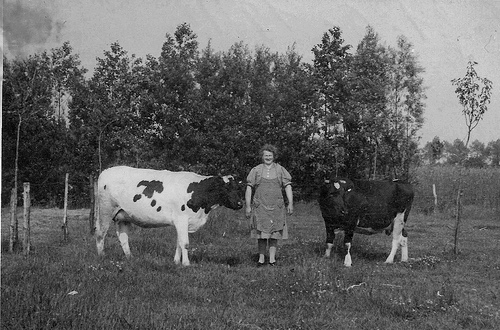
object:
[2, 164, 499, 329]
field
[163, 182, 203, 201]
black and white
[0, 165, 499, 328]
grass in  photo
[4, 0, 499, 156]
sky inphoto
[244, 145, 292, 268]
middle aged woman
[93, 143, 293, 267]
woman with a cow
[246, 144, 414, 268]
woman with a cow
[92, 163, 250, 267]
cows on grass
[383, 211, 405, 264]
cow with white legs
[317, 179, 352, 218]
black head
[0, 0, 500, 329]
picture of a farmer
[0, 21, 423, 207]
lots of trees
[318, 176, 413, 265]
black cow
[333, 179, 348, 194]
black and white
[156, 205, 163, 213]
cow has spots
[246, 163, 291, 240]
milk maids outfit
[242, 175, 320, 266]
between two cows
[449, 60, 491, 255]
small new tree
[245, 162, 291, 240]
dress and apron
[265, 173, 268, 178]
buttons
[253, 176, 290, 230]
front of apron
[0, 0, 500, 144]
gray cloud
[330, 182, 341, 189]
little white spot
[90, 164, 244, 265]
big white cow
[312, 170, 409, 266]
small cow ina field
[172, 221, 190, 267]
with white legs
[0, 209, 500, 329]
short grass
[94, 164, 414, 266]
two cows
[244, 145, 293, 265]
blonde fat woman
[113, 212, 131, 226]
udder of the cow